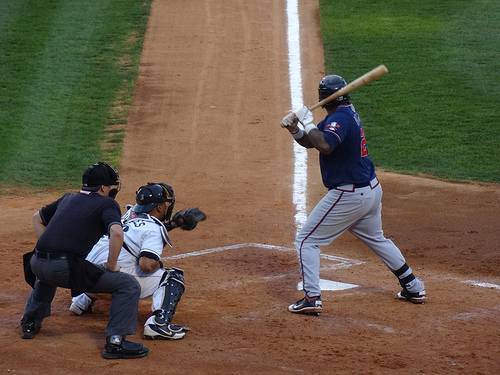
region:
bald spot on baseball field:
[95, 78, 125, 142]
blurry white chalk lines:
[344, 312, 461, 337]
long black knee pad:
[163, 267, 193, 332]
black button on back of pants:
[358, 188, 367, 202]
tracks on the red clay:
[191, 13, 285, 163]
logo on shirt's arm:
[318, 113, 349, 134]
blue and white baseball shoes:
[280, 293, 336, 317]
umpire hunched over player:
[11, 151, 171, 349]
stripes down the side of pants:
[288, 177, 340, 307]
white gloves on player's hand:
[297, 104, 324, 140]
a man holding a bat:
[255, 56, 406, 293]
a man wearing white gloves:
[287, 86, 319, 140]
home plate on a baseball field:
[283, 252, 363, 325]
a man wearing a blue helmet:
[319, 65, 353, 115]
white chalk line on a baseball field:
[264, 9, 309, 266]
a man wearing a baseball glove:
[171, 187, 209, 247]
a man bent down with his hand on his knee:
[57, 159, 125, 298]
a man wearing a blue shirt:
[305, 57, 382, 207]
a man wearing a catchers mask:
[124, 177, 176, 229]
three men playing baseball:
[34, 57, 418, 324]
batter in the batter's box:
[231, 32, 440, 359]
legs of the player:
[274, 213, 434, 303]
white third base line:
[259, 59, 315, 208]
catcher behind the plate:
[88, 158, 225, 315]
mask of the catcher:
[139, 173, 190, 224]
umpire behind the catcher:
[28, 135, 150, 312]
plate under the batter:
[300, 256, 371, 311]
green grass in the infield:
[409, 93, 483, 156]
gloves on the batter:
[274, 100, 324, 144]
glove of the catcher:
[168, 203, 215, 240]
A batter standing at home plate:
[269, 58, 430, 313]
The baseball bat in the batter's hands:
[282, 60, 391, 127]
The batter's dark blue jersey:
[298, 100, 379, 190]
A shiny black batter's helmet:
[314, 72, 354, 108]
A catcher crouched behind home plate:
[62, 177, 210, 340]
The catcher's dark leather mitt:
[166, 205, 212, 232]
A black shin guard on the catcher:
[141, 265, 189, 335]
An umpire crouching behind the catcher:
[15, 153, 149, 360]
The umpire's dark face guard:
[77, 158, 122, 201]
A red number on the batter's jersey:
[356, 127, 370, 162]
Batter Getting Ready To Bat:
[279, 61, 427, 315]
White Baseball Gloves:
[281, 105, 318, 139]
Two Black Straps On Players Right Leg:
[389, 263, 419, 287]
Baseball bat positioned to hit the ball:
[278, 63, 390, 129]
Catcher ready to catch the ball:
[70, 180, 207, 340]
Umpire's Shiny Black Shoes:
[101, 338, 147, 363]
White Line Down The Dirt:
[284, 0, 310, 244]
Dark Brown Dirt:
[316, 163, 498, 280]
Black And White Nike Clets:
[143, 320, 187, 341]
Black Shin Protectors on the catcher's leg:
[147, 265, 184, 329]